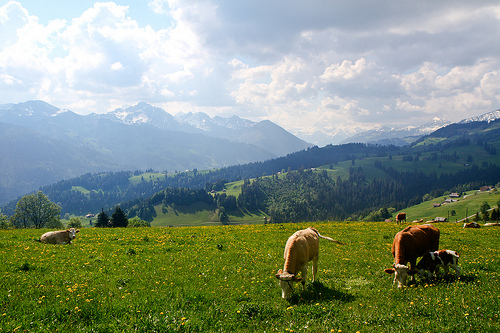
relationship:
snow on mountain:
[127, 91, 191, 117] [80, 62, 241, 156]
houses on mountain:
[395, 167, 491, 227] [80, 62, 241, 156]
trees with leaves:
[194, 169, 287, 209] [195, 184, 273, 227]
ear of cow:
[296, 259, 307, 288] [272, 212, 345, 330]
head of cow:
[272, 272, 303, 302] [272, 212, 345, 330]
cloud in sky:
[100, 20, 155, 76] [126, 17, 153, 43]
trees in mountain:
[194, 169, 287, 209] [80, 62, 241, 156]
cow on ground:
[272, 212, 345, 330] [256, 276, 344, 309]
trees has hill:
[194, 169, 287, 209] [64, 134, 206, 250]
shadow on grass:
[239, 296, 261, 319] [145, 228, 199, 325]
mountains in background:
[0, 90, 274, 122] [36, 15, 363, 201]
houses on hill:
[395, 167, 491, 227] [64, 134, 206, 250]